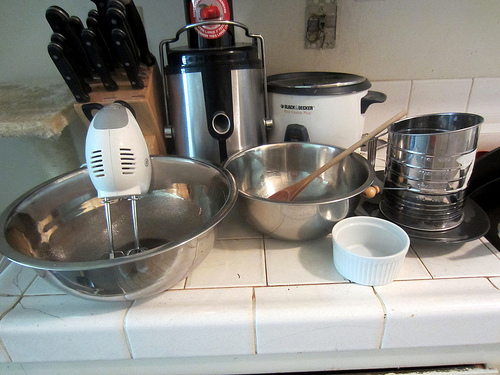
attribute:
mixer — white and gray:
[67, 88, 162, 219]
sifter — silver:
[363, 111, 490, 242]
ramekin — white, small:
[329, 212, 410, 283]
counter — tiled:
[0, 212, 499, 372]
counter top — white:
[3, 195, 498, 374]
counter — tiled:
[0, 190, 498, 374]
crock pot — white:
[259, 65, 388, 165]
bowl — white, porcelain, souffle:
[325, 211, 410, 286]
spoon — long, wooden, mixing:
[261, 109, 409, 200]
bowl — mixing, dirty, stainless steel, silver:
[2, 151, 239, 303]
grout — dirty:
[215, 239, 309, 301]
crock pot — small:
[265, 66, 386, 148]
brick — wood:
[72, 61, 164, 152]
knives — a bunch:
[41, 0, 149, 89]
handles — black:
[65, 21, 139, 83]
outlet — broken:
[299, 0, 338, 52]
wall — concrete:
[5, 4, 480, 80]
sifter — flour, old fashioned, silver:
[375, 109, 484, 232]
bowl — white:
[331, 210, 412, 286]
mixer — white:
[83, 101, 153, 203]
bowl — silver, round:
[228, 138, 379, 244]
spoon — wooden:
[271, 104, 411, 197]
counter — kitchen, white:
[189, 230, 480, 353]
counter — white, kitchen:
[218, 235, 365, 372]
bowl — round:
[330, 213, 411, 290]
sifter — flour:
[366, 106, 485, 229]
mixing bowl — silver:
[2, 151, 241, 303]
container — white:
[330, 213, 411, 287]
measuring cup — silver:
[369, 110, 484, 234]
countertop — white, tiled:
[2, 207, 484, 364]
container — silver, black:
[157, 20, 274, 167]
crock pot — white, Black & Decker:
[263, 70, 387, 155]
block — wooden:
[72, 59, 169, 157]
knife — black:
[45, 40, 90, 102]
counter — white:
[1, 204, 483, 363]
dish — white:
[329, 214, 409, 286]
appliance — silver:
[156, 15, 275, 166]